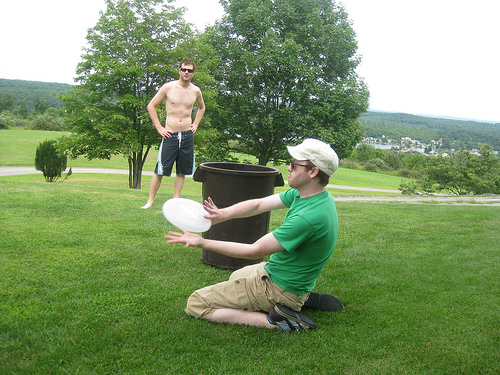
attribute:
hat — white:
[287, 138, 340, 176]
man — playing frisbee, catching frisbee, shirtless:
[164, 138, 342, 330]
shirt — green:
[265, 189, 339, 294]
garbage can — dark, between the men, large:
[193, 162, 284, 271]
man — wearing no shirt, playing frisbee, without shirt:
[142, 59, 207, 214]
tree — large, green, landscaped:
[201, 1, 369, 166]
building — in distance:
[412, 140, 420, 146]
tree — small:
[371, 149, 386, 165]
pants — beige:
[185, 261, 313, 320]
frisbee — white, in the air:
[162, 198, 212, 233]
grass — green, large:
[0, 129, 498, 375]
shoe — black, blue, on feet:
[268, 305, 318, 333]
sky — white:
[1, 2, 499, 123]